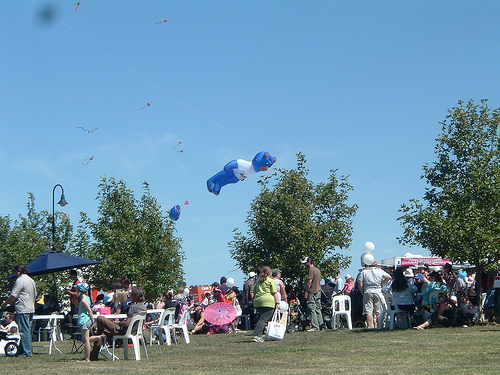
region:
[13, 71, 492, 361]
this is a party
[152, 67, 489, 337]
this is a public event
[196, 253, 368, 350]
people are having a good time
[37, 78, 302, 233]
some people are flying kites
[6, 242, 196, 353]
this is a crowd of people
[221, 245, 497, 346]
a public event filled with people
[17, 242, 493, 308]
an outdoor birthday party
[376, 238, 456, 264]
some kind of tent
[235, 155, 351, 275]
a tree near the partygoers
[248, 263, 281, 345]
this lady wears a yellow shirt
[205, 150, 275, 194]
blue balloon bear in sky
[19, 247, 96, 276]
open umbrella is blue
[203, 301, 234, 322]
pink umbrella is open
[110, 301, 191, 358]
three plastic white lawn chairs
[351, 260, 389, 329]
man wearing tan shorts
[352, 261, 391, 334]
man wearing white shirt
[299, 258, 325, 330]
man wearing green pants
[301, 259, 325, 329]
man wearing brown shirt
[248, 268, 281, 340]
woman wearing green shirt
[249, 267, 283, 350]
woman wearing black pants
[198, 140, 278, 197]
blue bear kite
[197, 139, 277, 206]
blue and white kite in sky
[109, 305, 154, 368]
white plastic lawn chair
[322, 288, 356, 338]
white plastic chair on grass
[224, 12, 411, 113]
clear blue cloudless sky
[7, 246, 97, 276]
navy blue umbrella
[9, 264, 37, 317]
man wearing grey shirt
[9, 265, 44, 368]
man wearing blue jeans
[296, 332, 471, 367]
green grassy lawn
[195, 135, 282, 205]
blue teddy in the air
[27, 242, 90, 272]
blue umbrella hanging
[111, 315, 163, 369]
white lawn chair to sit in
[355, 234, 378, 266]
white balloons in the air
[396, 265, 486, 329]
bunch of people watching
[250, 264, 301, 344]
woman with a green shirt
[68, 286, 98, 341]
girl in green outfit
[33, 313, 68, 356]
white table below the umbrella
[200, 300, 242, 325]
pink umbrella being hold by a person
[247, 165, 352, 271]
green tree in middle of the crowd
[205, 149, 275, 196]
A blue balloon shaped as a Teddy bear.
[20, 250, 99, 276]
A very large blue umbrella.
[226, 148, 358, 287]
A large tree is in a beautiful park.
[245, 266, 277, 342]
A chubby white woman is at the park.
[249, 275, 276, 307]
The chubby woman is wearing a green shirt.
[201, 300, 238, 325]
The pink umbrella is used on the floor.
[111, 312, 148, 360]
A white plastic chair is in the park.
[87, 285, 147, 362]
A young white man is sitting in a chair.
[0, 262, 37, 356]
A guy is turning his back.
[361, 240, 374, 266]
Two white balloons are in this park.